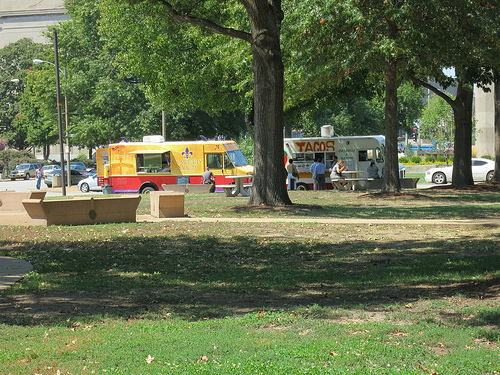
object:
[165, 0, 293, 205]
tree trunk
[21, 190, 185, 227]
benches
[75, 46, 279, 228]
park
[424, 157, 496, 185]
car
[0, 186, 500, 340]
grass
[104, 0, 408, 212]
tree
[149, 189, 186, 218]
bench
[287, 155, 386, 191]
people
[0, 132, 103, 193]
lot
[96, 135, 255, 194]
truck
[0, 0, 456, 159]
trees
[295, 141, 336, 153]
letters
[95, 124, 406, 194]
trucks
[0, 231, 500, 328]
shadow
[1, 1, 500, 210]
trees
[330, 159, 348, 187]
person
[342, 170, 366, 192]
table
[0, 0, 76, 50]
building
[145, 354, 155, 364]
leaf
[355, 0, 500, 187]
tree